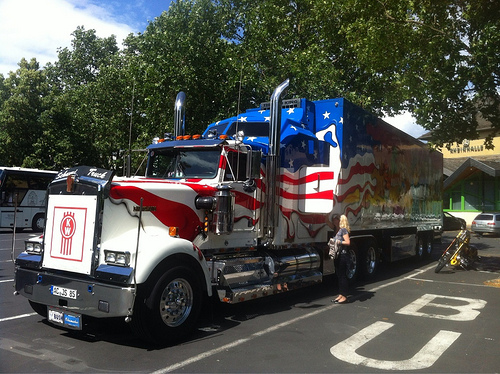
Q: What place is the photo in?
A: It is at the parking lot.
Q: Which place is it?
A: It is a parking lot.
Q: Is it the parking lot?
A: Yes, it is the parking lot.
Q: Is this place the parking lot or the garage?
A: It is the parking lot.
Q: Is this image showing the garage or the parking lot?
A: It is showing the parking lot.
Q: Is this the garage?
A: No, it is the parking lot.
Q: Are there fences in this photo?
A: No, there are no fences.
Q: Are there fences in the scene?
A: No, there are no fences.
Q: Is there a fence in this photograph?
A: No, there are no fences.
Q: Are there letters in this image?
A: Yes, there are letters.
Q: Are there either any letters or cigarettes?
A: Yes, there are letters.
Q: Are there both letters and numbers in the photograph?
A: No, there are letters but no numbers.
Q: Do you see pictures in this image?
A: No, there are no pictures.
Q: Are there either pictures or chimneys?
A: No, there are no pictures or chimneys.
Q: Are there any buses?
A: Yes, there is a bus.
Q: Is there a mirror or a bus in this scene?
A: Yes, there is a bus.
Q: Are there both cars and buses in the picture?
A: Yes, there are both a bus and a car.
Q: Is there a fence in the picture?
A: No, there are no fences.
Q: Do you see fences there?
A: No, there are no fences.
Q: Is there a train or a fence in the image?
A: No, there are no fences or trains.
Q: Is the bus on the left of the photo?
A: Yes, the bus is on the left of the image.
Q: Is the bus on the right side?
A: No, the bus is on the left of the image.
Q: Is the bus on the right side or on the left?
A: The bus is on the left of the image.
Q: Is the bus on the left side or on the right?
A: The bus is on the left of the image.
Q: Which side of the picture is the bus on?
A: The bus is on the left of the image.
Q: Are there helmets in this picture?
A: No, there are no helmets.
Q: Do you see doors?
A: Yes, there is a door.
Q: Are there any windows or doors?
A: Yes, there is a door.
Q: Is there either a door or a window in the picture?
A: Yes, there is a door.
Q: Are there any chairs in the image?
A: No, there are no chairs.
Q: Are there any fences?
A: No, there are no fences.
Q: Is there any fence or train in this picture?
A: No, there are no fences or trains.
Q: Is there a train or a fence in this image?
A: No, there are no fences or trains.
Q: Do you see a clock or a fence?
A: No, there are no fences or clocks.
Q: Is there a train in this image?
A: No, there are no trains.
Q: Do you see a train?
A: No, there are no trains.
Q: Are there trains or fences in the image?
A: No, there are no trains or fences.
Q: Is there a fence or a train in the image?
A: No, there are no trains or fences.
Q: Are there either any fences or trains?
A: No, there are no trains or fences.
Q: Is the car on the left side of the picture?
A: No, the car is on the right of the image.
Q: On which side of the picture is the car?
A: The car is on the right of the image.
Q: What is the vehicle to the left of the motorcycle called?
A: The vehicle is a car.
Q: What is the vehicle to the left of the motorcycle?
A: The vehicle is a car.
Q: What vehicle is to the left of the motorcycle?
A: The vehicle is a car.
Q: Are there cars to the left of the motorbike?
A: Yes, there is a car to the left of the motorbike.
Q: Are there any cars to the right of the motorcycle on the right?
A: No, the car is to the left of the motorbike.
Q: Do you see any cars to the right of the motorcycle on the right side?
A: No, the car is to the left of the motorbike.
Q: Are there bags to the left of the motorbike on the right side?
A: No, there is a car to the left of the motorcycle.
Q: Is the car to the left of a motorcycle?
A: Yes, the car is to the left of a motorcycle.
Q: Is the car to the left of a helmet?
A: No, the car is to the left of a motorcycle.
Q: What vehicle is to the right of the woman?
A: The vehicle is a car.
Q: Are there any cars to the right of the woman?
A: Yes, there is a car to the right of the woman.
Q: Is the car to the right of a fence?
A: No, the car is to the right of the woman.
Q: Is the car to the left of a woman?
A: No, the car is to the right of a woman.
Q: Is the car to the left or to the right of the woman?
A: The car is to the right of the woman.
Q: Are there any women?
A: Yes, there is a woman.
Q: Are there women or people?
A: Yes, there is a woman.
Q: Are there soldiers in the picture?
A: No, there are no soldiers.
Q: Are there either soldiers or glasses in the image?
A: No, there are no soldiers or glasses.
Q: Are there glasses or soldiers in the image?
A: No, there are no soldiers or glasses.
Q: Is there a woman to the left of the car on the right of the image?
A: Yes, there is a woman to the left of the car.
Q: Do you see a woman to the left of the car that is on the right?
A: Yes, there is a woman to the left of the car.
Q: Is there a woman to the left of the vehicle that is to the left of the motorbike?
A: Yes, there is a woman to the left of the car.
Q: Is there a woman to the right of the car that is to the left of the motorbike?
A: No, the woman is to the left of the car.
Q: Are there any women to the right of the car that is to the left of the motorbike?
A: No, the woman is to the left of the car.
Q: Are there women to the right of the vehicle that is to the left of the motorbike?
A: No, the woman is to the left of the car.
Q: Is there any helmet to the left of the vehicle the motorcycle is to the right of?
A: No, there is a woman to the left of the car.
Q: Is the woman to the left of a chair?
A: No, the woman is to the left of the car.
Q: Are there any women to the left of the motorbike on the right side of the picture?
A: Yes, there is a woman to the left of the motorbike.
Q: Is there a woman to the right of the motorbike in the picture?
A: No, the woman is to the left of the motorbike.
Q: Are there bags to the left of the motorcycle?
A: No, there is a woman to the left of the motorcycle.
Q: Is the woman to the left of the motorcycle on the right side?
A: Yes, the woman is to the left of the motorbike.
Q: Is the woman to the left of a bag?
A: No, the woman is to the left of the motorbike.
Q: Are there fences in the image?
A: No, there are no fences.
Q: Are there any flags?
A: Yes, there is a flag.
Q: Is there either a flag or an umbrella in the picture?
A: Yes, there is a flag.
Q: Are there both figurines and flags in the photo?
A: No, there is a flag but no figurines.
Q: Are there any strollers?
A: No, there are no strollers.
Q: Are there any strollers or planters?
A: No, there are no strollers or planters.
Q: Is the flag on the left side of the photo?
A: Yes, the flag is on the left of the image.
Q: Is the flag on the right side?
A: No, the flag is on the left of the image.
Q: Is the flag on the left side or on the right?
A: The flag is on the left of the image.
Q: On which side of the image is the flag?
A: The flag is on the left of the image.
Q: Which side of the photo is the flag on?
A: The flag is on the left of the image.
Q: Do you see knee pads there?
A: No, there are no knee pads.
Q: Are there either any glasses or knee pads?
A: No, there are no knee pads or glasses.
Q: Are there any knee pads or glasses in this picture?
A: No, there are no knee pads or glasses.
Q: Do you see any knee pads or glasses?
A: No, there are no knee pads or glasses.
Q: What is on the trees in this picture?
A: The leaves are on the trees.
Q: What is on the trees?
A: The leaves are on the trees.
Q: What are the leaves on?
A: The leaves are on the trees.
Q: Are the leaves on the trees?
A: Yes, the leaves are on the trees.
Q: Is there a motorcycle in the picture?
A: Yes, there is a motorcycle.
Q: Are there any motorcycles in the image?
A: Yes, there is a motorcycle.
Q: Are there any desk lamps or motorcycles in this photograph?
A: Yes, there is a motorcycle.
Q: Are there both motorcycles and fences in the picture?
A: No, there is a motorcycle but no fences.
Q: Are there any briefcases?
A: No, there are no briefcases.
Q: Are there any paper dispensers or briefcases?
A: No, there are no briefcases or paper dispensers.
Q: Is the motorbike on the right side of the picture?
A: Yes, the motorbike is on the right of the image.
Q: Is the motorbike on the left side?
A: No, the motorbike is on the right of the image.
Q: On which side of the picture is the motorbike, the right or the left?
A: The motorbike is on the right of the image.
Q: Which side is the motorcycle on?
A: The motorcycle is on the right of the image.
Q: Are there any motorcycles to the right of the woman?
A: Yes, there is a motorcycle to the right of the woman.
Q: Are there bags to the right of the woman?
A: No, there is a motorcycle to the right of the woman.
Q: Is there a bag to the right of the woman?
A: No, there is a motorcycle to the right of the woman.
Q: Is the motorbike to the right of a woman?
A: Yes, the motorbike is to the right of a woman.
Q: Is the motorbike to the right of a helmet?
A: No, the motorbike is to the right of a woman.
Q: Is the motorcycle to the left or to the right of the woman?
A: The motorcycle is to the right of the woman.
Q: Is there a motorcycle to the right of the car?
A: Yes, there is a motorcycle to the right of the car.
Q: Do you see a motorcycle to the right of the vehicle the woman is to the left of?
A: Yes, there is a motorcycle to the right of the car.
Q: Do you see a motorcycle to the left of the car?
A: No, the motorcycle is to the right of the car.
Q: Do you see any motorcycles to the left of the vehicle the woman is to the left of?
A: No, the motorcycle is to the right of the car.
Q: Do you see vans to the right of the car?
A: No, there is a motorcycle to the right of the car.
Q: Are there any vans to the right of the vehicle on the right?
A: No, there is a motorcycle to the right of the car.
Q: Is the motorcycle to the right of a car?
A: Yes, the motorcycle is to the right of a car.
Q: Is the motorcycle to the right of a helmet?
A: No, the motorcycle is to the right of a car.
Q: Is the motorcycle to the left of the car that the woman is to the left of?
A: No, the motorcycle is to the right of the car.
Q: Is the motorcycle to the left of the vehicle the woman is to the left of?
A: No, the motorcycle is to the right of the car.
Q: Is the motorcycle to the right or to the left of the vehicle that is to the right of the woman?
A: The motorcycle is to the right of the car.